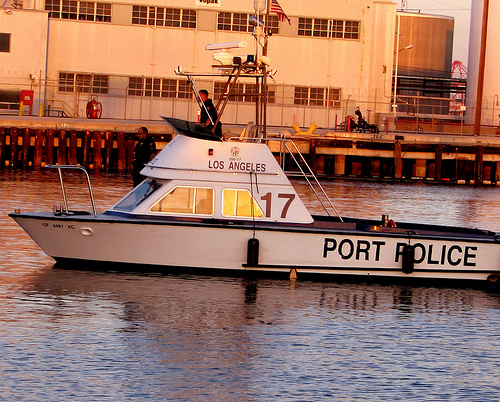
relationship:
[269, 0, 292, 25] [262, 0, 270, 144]
flag on pole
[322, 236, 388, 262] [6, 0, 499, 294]
word port on side of boat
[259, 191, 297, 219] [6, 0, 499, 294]
number 17 on side of boat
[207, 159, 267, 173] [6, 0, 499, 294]
los angeles on boat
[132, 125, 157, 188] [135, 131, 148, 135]
police officer wearing glasses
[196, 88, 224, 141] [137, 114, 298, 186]
police officer on upper deck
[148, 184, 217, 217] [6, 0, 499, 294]
window on boat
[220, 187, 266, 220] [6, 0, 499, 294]
window on boat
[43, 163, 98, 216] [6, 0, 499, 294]
railing on boat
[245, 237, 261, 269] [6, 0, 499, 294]
anchor on boat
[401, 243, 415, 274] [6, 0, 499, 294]
anchor on boat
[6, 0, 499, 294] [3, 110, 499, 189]
boat in harbor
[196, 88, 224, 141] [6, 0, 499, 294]
police officer on boat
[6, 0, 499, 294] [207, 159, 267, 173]
boat from los angeles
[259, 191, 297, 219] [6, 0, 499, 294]
number 17 on boat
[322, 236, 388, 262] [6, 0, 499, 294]
word port on boat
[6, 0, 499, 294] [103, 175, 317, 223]
boat has cabin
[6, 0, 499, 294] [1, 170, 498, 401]
boat in water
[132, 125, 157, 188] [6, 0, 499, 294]
police officer driving boat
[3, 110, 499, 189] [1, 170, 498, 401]
harbor in water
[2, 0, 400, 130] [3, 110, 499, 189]
building in harbor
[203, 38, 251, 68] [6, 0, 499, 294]
radar on boat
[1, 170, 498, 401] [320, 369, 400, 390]
water has ripples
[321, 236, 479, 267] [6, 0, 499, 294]
writing on side of boat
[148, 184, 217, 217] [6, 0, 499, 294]
window on side of boat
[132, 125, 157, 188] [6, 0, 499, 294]
police officer standing on boat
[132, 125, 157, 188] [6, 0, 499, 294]
police officer on boat